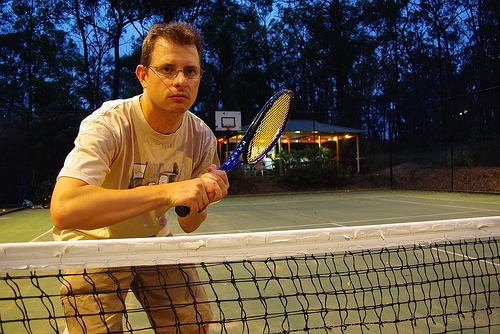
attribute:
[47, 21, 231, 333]
man — intense, playing, ready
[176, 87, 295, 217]
tennis racket — yellow, blue, black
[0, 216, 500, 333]
net — black, white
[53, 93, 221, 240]
shirt — white, tan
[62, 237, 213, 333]
shorts — beige, khaki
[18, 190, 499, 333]
court — lit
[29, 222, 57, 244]
paint — white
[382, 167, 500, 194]
ground — mud covered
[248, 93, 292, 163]
webbing — yellow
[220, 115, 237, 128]
box — red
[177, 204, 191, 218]
handle — black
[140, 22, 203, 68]
hair — brown